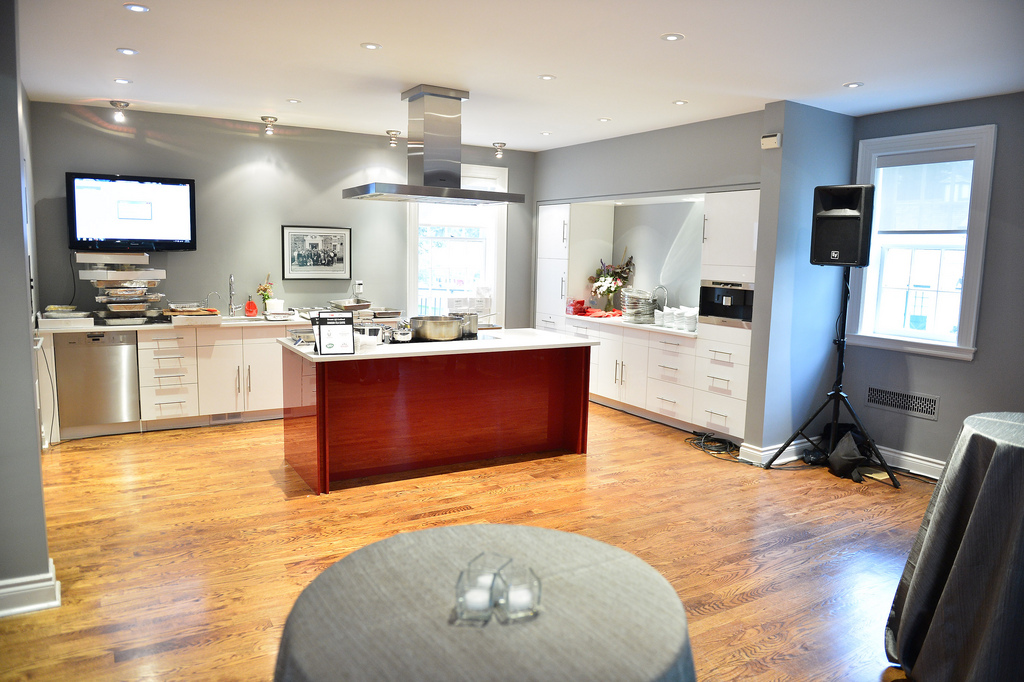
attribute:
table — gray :
[253, 488, 745, 672]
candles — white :
[457, 533, 531, 622]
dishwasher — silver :
[49, 325, 135, 440]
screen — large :
[67, 172, 188, 255]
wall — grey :
[765, 106, 1000, 470]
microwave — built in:
[689, 273, 759, 330]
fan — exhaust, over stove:
[333, 69, 524, 205]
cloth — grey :
[277, 513, 699, 672]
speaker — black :
[766, 173, 902, 486]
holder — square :
[497, 567, 537, 629]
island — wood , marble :
[279, 318, 587, 489]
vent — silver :
[336, 81, 526, 211]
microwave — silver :
[693, 274, 757, 333]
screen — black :
[57, 163, 197, 247]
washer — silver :
[38, 328, 146, 440]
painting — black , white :
[276, 219, 356, 283]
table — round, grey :
[256, 517, 697, 680]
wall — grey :
[858, 382, 942, 427]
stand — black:
[763, 395, 903, 485]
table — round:
[322, 541, 631, 671]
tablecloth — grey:
[899, 440, 1014, 654]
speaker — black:
[813, 183, 870, 272]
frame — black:
[271, 217, 367, 297]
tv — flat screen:
[59, 167, 202, 261]